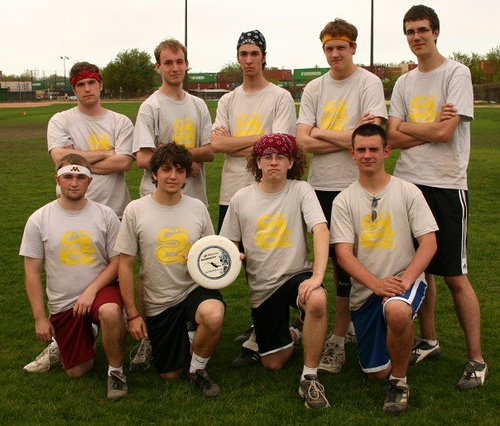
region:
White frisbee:
[186, 234, 243, 288]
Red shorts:
[47, 282, 123, 369]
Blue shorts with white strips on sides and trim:
[349, 280, 428, 374]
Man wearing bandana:
[220, 131, 333, 410]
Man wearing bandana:
[209, 30, 299, 362]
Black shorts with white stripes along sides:
[389, 182, 469, 276]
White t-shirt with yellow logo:
[17, 199, 125, 313]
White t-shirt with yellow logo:
[112, 193, 218, 317]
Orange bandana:
[320, 31, 355, 45]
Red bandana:
[68, 67, 103, 85]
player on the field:
[326, 123, 445, 400]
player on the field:
[236, 138, 334, 389]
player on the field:
[138, 143, 235, 395]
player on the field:
[7, 160, 148, 390]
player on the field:
[62, 66, 146, 201]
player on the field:
[143, 40, 218, 177]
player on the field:
[217, 35, 299, 135]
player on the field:
[291, 28, 370, 128]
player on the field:
[391, 6, 479, 190]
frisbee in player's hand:
[189, 237, 244, 295]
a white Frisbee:
[186, 231, 238, 286]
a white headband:
[55, 160, 90, 176]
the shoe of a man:
[375, 370, 412, 410]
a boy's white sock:
[301, 362, 317, 375]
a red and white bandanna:
[250, 133, 294, 155]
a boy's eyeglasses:
[403, 23, 435, 40]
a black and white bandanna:
[235, 28, 268, 53]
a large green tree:
[115, 47, 159, 92]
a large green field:
[1, 100, 498, 424]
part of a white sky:
[2, 26, 114, 62]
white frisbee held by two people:
[177, 226, 249, 302]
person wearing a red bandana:
[254, 130, 296, 181]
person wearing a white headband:
[50, 163, 94, 179]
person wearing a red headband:
[65, 65, 102, 82]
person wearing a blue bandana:
[239, 29, 273, 57]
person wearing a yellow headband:
[317, 31, 362, 47]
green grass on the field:
[17, 380, 82, 407]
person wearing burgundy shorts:
[23, 288, 124, 367]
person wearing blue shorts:
[350, 288, 435, 376]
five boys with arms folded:
[51, 10, 493, 171]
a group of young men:
[28, 0, 482, 397]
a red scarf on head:
[253, 136, 298, 154]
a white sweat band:
[55, 161, 100, 180]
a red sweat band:
[71, 71, 100, 85]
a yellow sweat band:
[323, 31, 358, 43]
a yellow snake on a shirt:
[156, 213, 192, 266]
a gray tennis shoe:
[185, 362, 221, 392]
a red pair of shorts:
[50, 280, 115, 370]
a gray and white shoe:
[450, 360, 490, 385]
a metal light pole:
[57, 53, 72, 92]